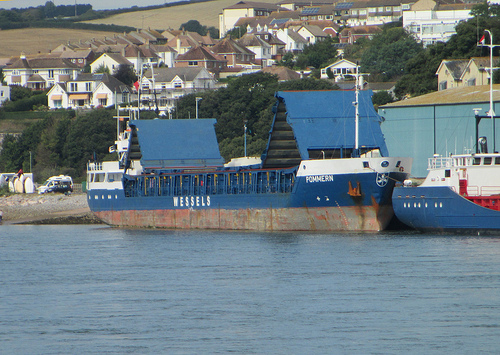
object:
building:
[401, 0, 485, 48]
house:
[173, 45, 228, 79]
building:
[45, 73, 135, 112]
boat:
[84, 156, 411, 232]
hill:
[0, 0, 248, 56]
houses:
[433, 55, 499, 93]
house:
[0, 51, 83, 104]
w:
[173, 196, 179, 207]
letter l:
[200, 195, 206, 206]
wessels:
[170, 195, 212, 207]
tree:
[66, 109, 118, 179]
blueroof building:
[260, 89, 390, 169]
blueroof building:
[123, 118, 226, 175]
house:
[124, 42, 162, 75]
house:
[272, 27, 308, 55]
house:
[88, 51, 136, 75]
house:
[318, 55, 364, 82]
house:
[233, 28, 286, 68]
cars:
[45, 179, 74, 195]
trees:
[0, 114, 67, 172]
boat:
[391, 152, 499, 229]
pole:
[489, 36, 494, 111]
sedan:
[38, 174, 73, 195]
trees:
[168, 72, 279, 159]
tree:
[362, 22, 427, 84]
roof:
[296, 4, 337, 15]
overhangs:
[0, 117, 46, 133]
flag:
[478, 33, 486, 48]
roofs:
[26, 57, 71, 67]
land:
[0, 0, 499, 196]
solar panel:
[298, 7, 321, 16]